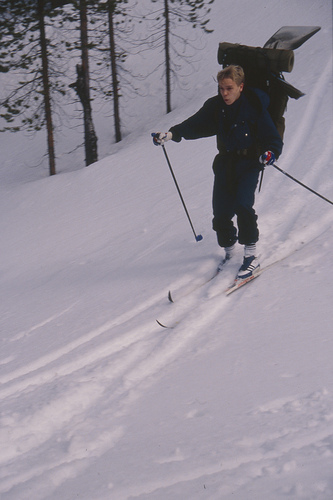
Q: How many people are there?
A: 1.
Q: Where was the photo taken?
A: Slopes.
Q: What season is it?
A: Winter.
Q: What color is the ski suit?
A: Blue.